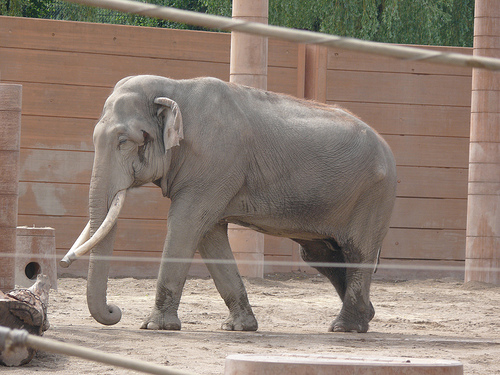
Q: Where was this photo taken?
A: At an animal exhibit.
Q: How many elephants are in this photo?
A: One.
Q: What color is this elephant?
A: Gray.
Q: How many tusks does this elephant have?
A: Two.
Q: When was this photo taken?
A: Outside, during the daytime.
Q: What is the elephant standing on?
A: Dirt.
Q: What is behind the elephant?
A: A wooden wall.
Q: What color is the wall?
A: Brown.